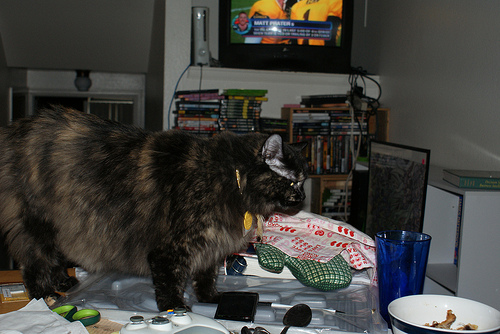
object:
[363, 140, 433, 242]
poster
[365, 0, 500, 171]
wall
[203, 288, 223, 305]
paw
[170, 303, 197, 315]
paw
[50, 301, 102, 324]
scissors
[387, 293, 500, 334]
bowl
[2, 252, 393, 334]
table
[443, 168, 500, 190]
book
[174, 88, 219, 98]
video games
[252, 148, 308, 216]
face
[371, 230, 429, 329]
glass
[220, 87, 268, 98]
dvds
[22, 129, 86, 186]
fur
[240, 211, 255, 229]
tag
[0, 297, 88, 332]
paper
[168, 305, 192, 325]
game controller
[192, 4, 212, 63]
game console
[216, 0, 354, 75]
tv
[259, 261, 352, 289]
section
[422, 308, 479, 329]
food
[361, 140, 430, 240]
frame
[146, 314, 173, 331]
controller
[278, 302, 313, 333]
spoon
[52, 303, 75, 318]
handle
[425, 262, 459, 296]
shelf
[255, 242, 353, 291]
mitt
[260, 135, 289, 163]
ear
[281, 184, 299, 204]
nose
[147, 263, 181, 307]
leg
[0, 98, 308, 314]
cat